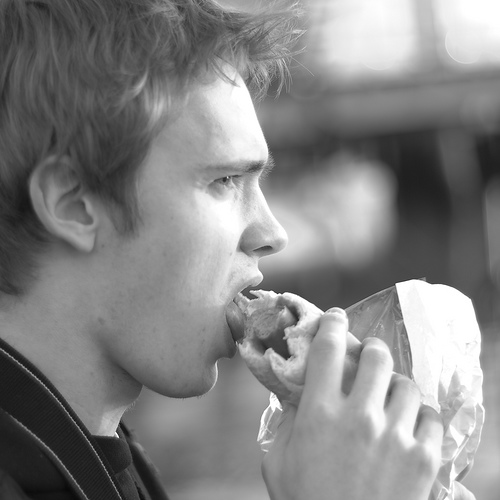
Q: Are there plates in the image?
A: No, there are no plates.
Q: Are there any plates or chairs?
A: No, there are no plates or chairs.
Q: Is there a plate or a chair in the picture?
A: No, there are no plates or chairs.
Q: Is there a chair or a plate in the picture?
A: No, there are no plates or chairs.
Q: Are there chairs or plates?
A: No, there are no plates or chairs.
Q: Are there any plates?
A: No, there are no plates.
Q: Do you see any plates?
A: No, there are no plates.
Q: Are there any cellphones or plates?
A: No, there are no plates or cellphones.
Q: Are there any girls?
A: No, there are no girls.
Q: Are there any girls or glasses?
A: No, there are no girls or glasses.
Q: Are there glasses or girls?
A: No, there are no girls or glasses.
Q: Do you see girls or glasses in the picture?
A: No, there are no girls or glasses.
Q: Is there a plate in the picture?
A: No, there are no plates.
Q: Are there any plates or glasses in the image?
A: No, there are no plates or glasses.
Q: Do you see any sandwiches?
A: Yes, there is a sandwich.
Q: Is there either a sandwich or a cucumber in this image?
A: Yes, there is a sandwich.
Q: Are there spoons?
A: No, there are no spoons.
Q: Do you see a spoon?
A: No, there are no spoons.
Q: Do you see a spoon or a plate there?
A: No, there are no spoons or plates.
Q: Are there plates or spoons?
A: No, there are no spoons or plates.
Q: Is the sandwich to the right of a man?
A: Yes, the sandwich is to the right of a man.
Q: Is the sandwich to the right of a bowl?
A: No, the sandwich is to the right of a man.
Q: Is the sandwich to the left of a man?
A: No, the sandwich is to the right of a man.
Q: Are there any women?
A: No, there are no women.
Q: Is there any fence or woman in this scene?
A: No, there are no women or fences.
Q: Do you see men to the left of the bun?
A: Yes, there is a man to the left of the bun.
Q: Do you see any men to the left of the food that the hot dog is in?
A: Yes, there is a man to the left of the bun.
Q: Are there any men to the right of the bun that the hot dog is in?
A: No, the man is to the left of the bun.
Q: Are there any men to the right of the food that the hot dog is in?
A: No, the man is to the left of the bun.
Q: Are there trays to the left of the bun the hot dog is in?
A: No, there is a man to the left of the bun.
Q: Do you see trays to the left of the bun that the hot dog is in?
A: No, there is a man to the left of the bun.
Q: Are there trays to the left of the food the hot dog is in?
A: No, there is a man to the left of the bun.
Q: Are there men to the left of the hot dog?
A: Yes, there is a man to the left of the hot dog.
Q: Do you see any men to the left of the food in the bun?
A: Yes, there is a man to the left of the hot dog.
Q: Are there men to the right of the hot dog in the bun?
A: No, the man is to the left of the hot dog.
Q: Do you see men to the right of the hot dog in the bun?
A: No, the man is to the left of the hot dog.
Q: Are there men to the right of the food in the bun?
A: No, the man is to the left of the hot dog.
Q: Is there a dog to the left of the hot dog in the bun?
A: No, there is a man to the left of the hot dog.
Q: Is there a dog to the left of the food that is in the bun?
A: No, there is a man to the left of the hot dog.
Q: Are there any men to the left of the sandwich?
A: Yes, there is a man to the left of the sandwich.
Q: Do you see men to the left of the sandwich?
A: Yes, there is a man to the left of the sandwich.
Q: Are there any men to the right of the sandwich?
A: No, the man is to the left of the sandwich.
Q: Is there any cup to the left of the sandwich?
A: No, there is a man to the left of the sandwich.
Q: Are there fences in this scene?
A: No, there are no fences.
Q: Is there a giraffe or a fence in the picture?
A: No, there are no fences or giraffes.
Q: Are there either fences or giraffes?
A: No, there are no fences or giraffes.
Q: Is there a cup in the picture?
A: No, there are no cups.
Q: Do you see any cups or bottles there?
A: No, there are no cups or bottles.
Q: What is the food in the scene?
A: The food is a bun.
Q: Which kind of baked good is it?
A: The food is a bun.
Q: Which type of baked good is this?
A: This is a bun.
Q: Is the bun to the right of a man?
A: Yes, the bun is to the right of a man.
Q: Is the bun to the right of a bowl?
A: No, the bun is to the right of a man.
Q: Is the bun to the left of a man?
A: No, the bun is to the right of a man.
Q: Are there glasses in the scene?
A: No, there are no glasses.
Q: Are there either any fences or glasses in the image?
A: No, there are no glasses or fences.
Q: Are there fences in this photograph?
A: No, there are no fences.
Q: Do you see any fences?
A: No, there are no fences.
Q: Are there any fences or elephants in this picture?
A: No, there are no fences or elephants.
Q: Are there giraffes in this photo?
A: No, there are no giraffes.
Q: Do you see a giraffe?
A: No, there are no giraffes.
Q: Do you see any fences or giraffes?
A: No, there are no giraffes or fences.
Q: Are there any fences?
A: No, there are no fences.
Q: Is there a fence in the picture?
A: No, there are no fences.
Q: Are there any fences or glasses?
A: No, there are no fences or glasses.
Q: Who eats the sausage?
A: The man eats the sausage.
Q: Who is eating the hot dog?
A: The man is eating the hot dog.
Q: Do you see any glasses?
A: No, there are no glasses.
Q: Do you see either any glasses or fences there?
A: No, there are no glasses or fences.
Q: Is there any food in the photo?
A: Yes, there is food.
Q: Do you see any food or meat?
A: Yes, there is food.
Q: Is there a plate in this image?
A: No, there are no plates.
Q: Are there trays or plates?
A: No, there are no plates or trays.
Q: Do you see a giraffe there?
A: No, there are no giraffes.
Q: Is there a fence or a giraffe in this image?
A: No, there are no giraffes or fences.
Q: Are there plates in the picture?
A: No, there are no plates.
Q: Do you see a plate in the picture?
A: No, there are no plates.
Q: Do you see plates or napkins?
A: No, there are no plates or napkins.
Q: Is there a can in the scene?
A: No, there are no cans.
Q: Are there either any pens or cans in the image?
A: No, there are no cans or pens.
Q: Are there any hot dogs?
A: Yes, there is a hot dog.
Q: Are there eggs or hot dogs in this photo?
A: Yes, there is a hot dog.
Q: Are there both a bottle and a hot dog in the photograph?
A: No, there is a hot dog but no bottles.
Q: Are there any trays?
A: No, there are no trays.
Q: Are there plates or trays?
A: No, there are no trays or plates.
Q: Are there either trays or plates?
A: No, there are no trays or plates.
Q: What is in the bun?
A: The hot dog is in the bun.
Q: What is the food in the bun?
A: The food is a hot dog.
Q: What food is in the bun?
A: The food is a hot dog.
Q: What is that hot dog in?
A: The hot dog is in the bun.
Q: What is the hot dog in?
A: The hot dog is in the bun.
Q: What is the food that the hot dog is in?
A: The food is a bun.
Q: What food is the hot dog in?
A: The hot dog is in the bun.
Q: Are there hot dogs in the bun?
A: Yes, there is a hot dog in the bun.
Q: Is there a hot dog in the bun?
A: Yes, there is a hot dog in the bun.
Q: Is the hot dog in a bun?
A: Yes, the hot dog is in a bun.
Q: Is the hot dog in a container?
A: No, the hot dog is in a bun.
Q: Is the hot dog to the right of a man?
A: Yes, the hot dog is to the right of a man.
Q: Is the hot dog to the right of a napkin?
A: No, the hot dog is to the right of a man.